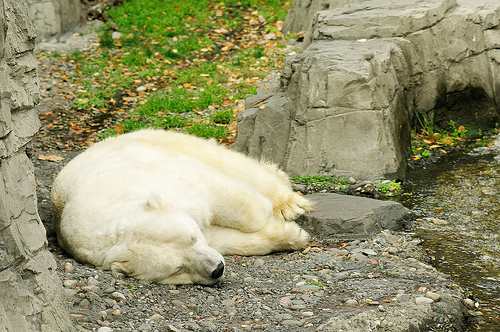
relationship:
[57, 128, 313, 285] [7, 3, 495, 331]
polar bear sleeping on ground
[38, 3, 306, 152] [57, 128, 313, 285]
grass behind polar bear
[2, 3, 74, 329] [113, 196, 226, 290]
cluster of stones near head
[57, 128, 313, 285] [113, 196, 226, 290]
polar bear has head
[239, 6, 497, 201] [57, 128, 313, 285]
rock emplacement near polar bear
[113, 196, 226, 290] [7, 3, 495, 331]
head lying on ground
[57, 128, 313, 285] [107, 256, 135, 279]
polar bear has right ear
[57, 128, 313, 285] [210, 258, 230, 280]
polar bear has nose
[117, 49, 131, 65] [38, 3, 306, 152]
leaf near grass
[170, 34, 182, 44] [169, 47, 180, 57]
leaf next to leaf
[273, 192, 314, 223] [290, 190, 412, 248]
foot on top of rock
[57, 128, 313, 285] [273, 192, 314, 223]
polar bear has foot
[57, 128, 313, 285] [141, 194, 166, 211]
polar bear has left ear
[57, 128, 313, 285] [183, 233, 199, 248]
polar bear has left eye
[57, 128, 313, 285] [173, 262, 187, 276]
polar bear has right eye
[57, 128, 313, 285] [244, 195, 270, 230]
polar bear has left paw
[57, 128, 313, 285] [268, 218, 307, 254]
polar bear has right paw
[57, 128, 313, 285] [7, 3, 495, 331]
polar bear laying on ground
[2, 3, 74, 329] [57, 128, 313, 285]
cluster of stones behind polar bear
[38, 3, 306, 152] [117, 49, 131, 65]
grass has leaf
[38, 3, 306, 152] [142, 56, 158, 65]
grass has leaf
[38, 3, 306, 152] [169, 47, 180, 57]
grass has leaf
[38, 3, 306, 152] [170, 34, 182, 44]
grass has leaf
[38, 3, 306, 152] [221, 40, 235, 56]
grass has leaf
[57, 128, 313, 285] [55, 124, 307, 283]
polar bear has fur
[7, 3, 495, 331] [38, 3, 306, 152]
ground has grass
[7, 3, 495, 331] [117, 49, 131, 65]
ground has leaf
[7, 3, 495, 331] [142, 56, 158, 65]
ground has leaf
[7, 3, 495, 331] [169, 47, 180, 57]
ground has leaf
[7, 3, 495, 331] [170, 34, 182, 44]
ground has leaf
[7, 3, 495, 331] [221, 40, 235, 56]
ground has leaf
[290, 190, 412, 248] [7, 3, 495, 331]
rock lying on ground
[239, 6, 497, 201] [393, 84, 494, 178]
rock has crevice